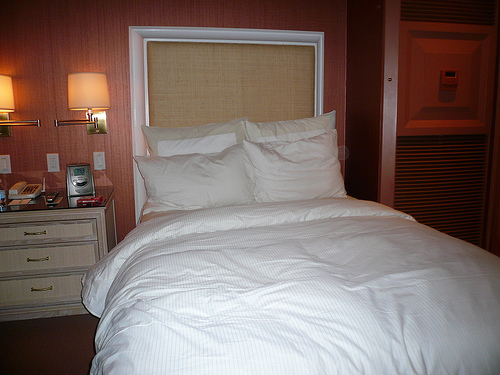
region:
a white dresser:
[5, 205, 105, 317]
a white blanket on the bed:
[131, 208, 478, 363]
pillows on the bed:
[133, 125, 353, 205]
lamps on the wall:
[5, 74, 132, 132]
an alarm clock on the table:
[68, 164, 90, 191]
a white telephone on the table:
[9, 178, 39, 195]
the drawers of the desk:
[6, 220, 111, 308]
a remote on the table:
[47, 189, 59, 204]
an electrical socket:
[47, 153, 61, 170]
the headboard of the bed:
[136, 30, 333, 122]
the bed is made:
[121, 112, 496, 367]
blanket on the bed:
[110, 198, 499, 371]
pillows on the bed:
[116, 104, 368, 201]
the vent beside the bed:
[392, 131, 499, 229]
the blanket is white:
[76, 187, 496, 374]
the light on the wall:
[42, 57, 122, 142]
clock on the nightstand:
[55, 160, 101, 197]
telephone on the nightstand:
[5, 172, 50, 198]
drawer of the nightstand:
[1, 215, 107, 243]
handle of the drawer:
[24, 228, 51, 241]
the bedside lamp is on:
[51, 70, 112, 133]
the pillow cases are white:
[136, 114, 341, 216]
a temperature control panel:
[436, 68, 460, 88]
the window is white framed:
[126, 23, 328, 220]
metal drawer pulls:
[24, 255, 49, 263]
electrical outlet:
[46, 153, 59, 173]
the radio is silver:
[66, 163, 96, 198]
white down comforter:
[88, 206, 499, 371]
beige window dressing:
[147, 43, 314, 125]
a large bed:
[93, 15, 483, 372]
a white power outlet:
[21, 144, 71, 180]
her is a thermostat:
[421, 55, 473, 102]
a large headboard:
[113, 0, 351, 219]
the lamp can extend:
[46, 50, 123, 156]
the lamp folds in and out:
[31, 45, 153, 167]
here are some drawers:
[5, 208, 130, 329]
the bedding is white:
[106, 101, 496, 371]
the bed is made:
[242, 235, 319, 286]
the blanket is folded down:
[184, 205, 230, 237]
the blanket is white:
[251, 262, 295, 304]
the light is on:
[77, 81, 100, 105]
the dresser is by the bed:
[86, 216, 141, 253]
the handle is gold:
[21, 229, 52, 240]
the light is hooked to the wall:
[51, 112, 79, 130]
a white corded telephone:
[5, 179, 40, 201]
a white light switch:
[90, 149, 107, 173]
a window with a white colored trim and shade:
[128, 24, 325, 222]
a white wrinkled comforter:
[79, 196, 497, 373]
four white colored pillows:
[133, 109, 347, 216]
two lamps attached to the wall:
[0, 71, 109, 134]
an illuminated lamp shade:
[65, 70, 112, 112]